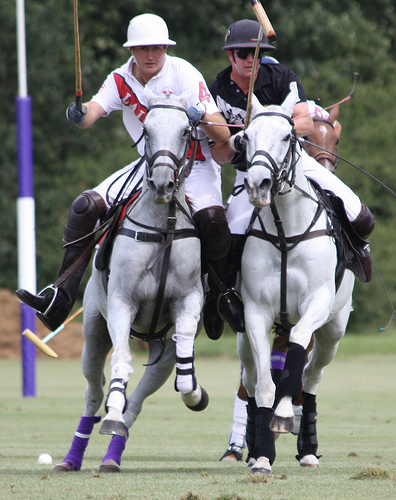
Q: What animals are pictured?
A: Horses.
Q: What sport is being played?
A: Polo.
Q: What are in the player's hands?
A: Mallets.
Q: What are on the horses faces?
A: Harnesses.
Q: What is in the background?
A: Trees.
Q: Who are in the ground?
A: Divets.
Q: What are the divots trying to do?
A: Trying to hit the ball.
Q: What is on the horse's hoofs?
A: Blue and black Wrap.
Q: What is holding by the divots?
A: Stick.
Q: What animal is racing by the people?
A: Horse.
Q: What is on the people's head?
A: Helmet.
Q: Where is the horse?
A: On the ground.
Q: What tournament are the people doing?
A: Polo tournament.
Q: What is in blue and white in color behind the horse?
A: A pole.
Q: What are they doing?
A: Polo.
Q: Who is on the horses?
A: Competitors.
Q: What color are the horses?
A: White.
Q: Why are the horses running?
A: They are in a polo match.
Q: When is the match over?
A: When one team wins.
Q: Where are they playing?
A: In the field.